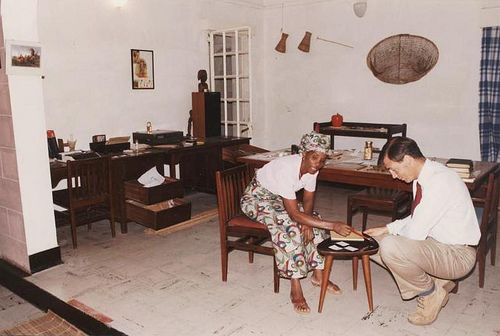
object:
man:
[363, 138, 482, 326]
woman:
[241, 133, 355, 314]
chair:
[214, 163, 283, 293]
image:
[130, 49, 155, 90]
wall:
[42, 0, 211, 151]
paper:
[137, 165, 166, 188]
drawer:
[122, 175, 183, 206]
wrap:
[300, 132, 334, 156]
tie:
[410, 182, 425, 218]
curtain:
[478, 25, 499, 164]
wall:
[255, 2, 500, 162]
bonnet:
[298, 133, 331, 154]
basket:
[367, 33, 440, 85]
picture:
[10, 44, 42, 68]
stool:
[316, 230, 380, 313]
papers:
[328, 241, 358, 252]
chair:
[53, 154, 117, 250]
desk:
[49, 135, 252, 197]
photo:
[9, 43, 41, 68]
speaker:
[190, 91, 222, 137]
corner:
[195, 0, 299, 36]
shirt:
[254, 154, 317, 200]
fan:
[367, 34, 440, 85]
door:
[209, 23, 253, 141]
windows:
[224, 54, 238, 100]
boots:
[408, 280, 457, 326]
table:
[316, 231, 380, 313]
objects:
[274, 31, 312, 54]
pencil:
[349, 227, 376, 244]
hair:
[377, 136, 424, 166]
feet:
[288, 277, 313, 313]